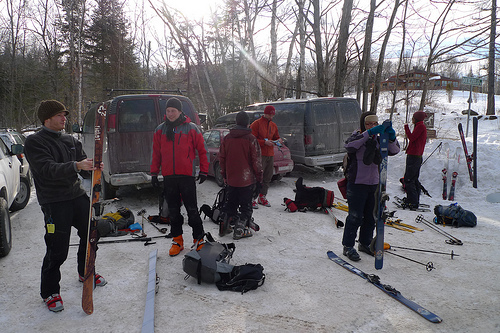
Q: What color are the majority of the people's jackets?
A: Red.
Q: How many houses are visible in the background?
A: Two.